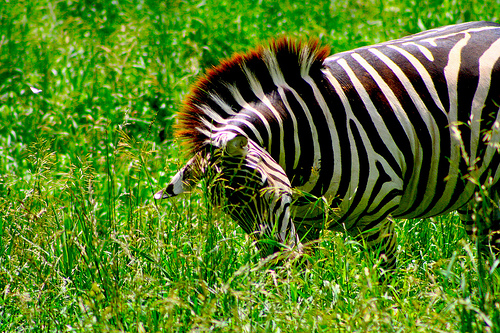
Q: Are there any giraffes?
A: No, there are no giraffes.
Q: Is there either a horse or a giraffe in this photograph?
A: No, there are no giraffes or horses.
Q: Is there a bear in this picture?
A: No, there are no bears.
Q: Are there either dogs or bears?
A: No, there are no bears or dogs.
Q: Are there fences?
A: No, there are no fences.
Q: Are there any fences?
A: No, there are no fences.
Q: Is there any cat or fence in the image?
A: No, there are no fences or cats.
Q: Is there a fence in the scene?
A: No, there are no fences.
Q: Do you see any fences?
A: No, there are no fences.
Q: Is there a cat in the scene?
A: No, there are no cats.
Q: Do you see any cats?
A: No, there are no cats.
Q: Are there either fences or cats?
A: No, there are no cats or fences.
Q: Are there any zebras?
A: Yes, there is a zebra.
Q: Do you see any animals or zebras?
A: Yes, there is a zebra.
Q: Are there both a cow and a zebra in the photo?
A: No, there is a zebra but no cows.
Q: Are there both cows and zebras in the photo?
A: No, there is a zebra but no cows.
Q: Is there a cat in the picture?
A: No, there are no cats.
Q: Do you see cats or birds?
A: No, there are no cats or birds.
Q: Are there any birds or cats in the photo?
A: No, there are no cats or birds.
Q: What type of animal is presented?
A: The animal is a zebra.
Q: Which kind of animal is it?
A: The animal is a zebra.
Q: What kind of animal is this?
A: That is a zebra.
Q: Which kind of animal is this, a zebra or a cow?
A: That is a zebra.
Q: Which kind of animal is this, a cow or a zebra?
A: That is a zebra.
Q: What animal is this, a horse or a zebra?
A: This is a zebra.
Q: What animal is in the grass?
A: The zebra is in the grass.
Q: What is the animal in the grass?
A: The animal is a zebra.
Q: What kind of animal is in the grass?
A: The animal is a zebra.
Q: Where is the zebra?
A: The zebra is in the grass.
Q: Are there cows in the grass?
A: No, there is a zebra in the grass.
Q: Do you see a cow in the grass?
A: No, there is a zebra in the grass.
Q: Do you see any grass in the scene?
A: Yes, there is grass.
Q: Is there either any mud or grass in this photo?
A: Yes, there is grass.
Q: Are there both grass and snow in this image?
A: No, there is grass but no snow.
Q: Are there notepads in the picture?
A: No, there are no notepads.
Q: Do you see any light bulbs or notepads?
A: No, there are no notepads or light bulbs.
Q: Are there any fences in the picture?
A: No, there are no fences.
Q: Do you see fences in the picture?
A: No, there are no fences.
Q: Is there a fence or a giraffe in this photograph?
A: No, there are no fences or giraffes.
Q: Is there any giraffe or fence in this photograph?
A: No, there are no fences or giraffes.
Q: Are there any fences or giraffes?
A: No, there are no fences or giraffes.